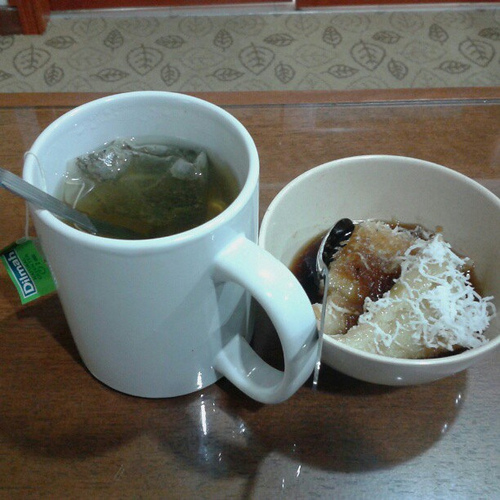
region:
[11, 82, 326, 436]
a white coffee mug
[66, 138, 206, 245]
a pouch of tea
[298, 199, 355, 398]
a metal spoon in a bowl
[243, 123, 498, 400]
a small white bowl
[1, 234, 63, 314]
the tag of a tea packet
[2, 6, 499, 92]
a floor with leaf pattern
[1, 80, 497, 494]
a wooden table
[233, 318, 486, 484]
the shadow of the bowl being cast on the table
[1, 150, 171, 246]
a spoon used for stirring tea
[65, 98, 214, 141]
condensation on the side of the mug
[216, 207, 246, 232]
edge of a chair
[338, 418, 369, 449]
part of a shade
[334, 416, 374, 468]
part of a shade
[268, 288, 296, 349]
part of a handle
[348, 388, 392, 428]
part of a table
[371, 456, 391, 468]
edge of a shade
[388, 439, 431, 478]
part of a table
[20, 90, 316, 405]
a white cup on a table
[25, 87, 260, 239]
green tea inside a white cup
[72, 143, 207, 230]
a tea bag inside a white cup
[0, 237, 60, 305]
a green tag hanging from a thread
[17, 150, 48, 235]
white thread of a tea bag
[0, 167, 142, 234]
handle of a teaspoon in a white cup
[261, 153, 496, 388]
a white bowl on a table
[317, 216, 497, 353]
grated cheese on a dumpling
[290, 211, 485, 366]
black coffee at the bottom of a bowl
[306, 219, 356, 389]
a teaspoon propped on a white bowl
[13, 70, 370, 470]
coffee mug on table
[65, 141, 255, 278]
green liquid in mug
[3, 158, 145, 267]
straw in the cup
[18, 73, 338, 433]
the coffee mug is white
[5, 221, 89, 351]
green bag behind cup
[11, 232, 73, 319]
the bag has tea in it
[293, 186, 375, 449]
spoon in the bowl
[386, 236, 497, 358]
white flakes on food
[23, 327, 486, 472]
shadow of bowl and cup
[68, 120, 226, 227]
ice in the tea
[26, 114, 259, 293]
tea bag in the cup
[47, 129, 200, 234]
tea bag in the cup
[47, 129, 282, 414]
tea bag in the cup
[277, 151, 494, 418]
the bowl is white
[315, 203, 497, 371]
white coconut shred on food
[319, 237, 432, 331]
white coconut shred on food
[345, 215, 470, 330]
white coconut shred on food